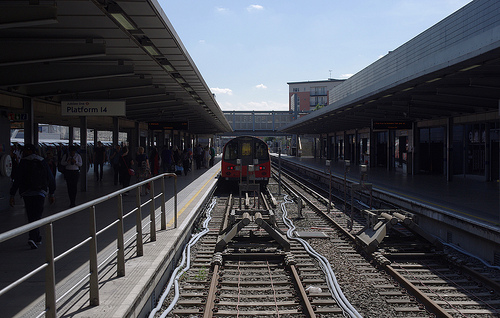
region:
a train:
[221, 136, 274, 184]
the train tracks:
[203, 267, 308, 300]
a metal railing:
[66, 205, 94, 217]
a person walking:
[17, 144, 49, 206]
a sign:
[63, 102, 125, 119]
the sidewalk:
[433, 187, 480, 207]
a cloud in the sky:
[252, 78, 269, 93]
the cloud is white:
[213, 81, 236, 96]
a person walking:
[59, 148, 85, 202]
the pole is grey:
[88, 250, 104, 298]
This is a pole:
[20, 87, 46, 224]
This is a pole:
[75, 97, 97, 197]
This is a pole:
[56, 102, 83, 184]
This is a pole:
[105, 90, 127, 192]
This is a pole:
[125, 103, 150, 203]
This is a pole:
[142, 107, 158, 193]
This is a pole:
[159, 108, 175, 177]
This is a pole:
[442, 106, 459, 194]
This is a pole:
[407, 104, 420, 197]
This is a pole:
[365, 105, 373, 195]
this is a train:
[216, 134, 274, 184]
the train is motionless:
[222, 133, 274, 185]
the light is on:
[259, 163, 269, 171]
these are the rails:
[409, 258, 447, 292]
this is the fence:
[94, 187, 149, 239]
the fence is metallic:
[117, 172, 173, 244]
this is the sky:
[221, 16, 303, 66]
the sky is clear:
[249, 8, 313, 49]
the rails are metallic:
[210, 220, 290, 262]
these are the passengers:
[42, 135, 119, 182]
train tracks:
[207, 275, 312, 317]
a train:
[222, 145, 268, 180]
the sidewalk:
[443, 177, 485, 200]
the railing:
[79, 200, 99, 208]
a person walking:
[16, 144, 53, 206]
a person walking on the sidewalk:
[58, 144, 88, 199]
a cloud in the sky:
[252, 80, 274, 93]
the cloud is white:
[246, 5, 267, 12]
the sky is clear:
[244, 34, 289, 64]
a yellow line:
[178, 196, 194, 211]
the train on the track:
[220, 135, 270, 190]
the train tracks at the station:
[167, 153, 498, 316]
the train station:
[0, 0, 497, 315]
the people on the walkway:
[0, 138, 214, 248]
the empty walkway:
[270, 107, 499, 227]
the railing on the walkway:
[0, 172, 177, 317]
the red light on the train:
[229, 165, 232, 168]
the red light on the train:
[257, 165, 262, 170]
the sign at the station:
[59, 99, 126, 116]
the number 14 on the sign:
[98, 104, 107, 114]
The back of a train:
[220, 138, 270, 190]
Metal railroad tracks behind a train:
[202, 188, 321, 317]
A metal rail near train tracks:
[1, 168, 178, 317]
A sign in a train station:
[62, 95, 130, 115]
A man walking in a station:
[17, 142, 51, 242]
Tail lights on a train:
[225, 162, 265, 174]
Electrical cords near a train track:
[282, 193, 362, 316]